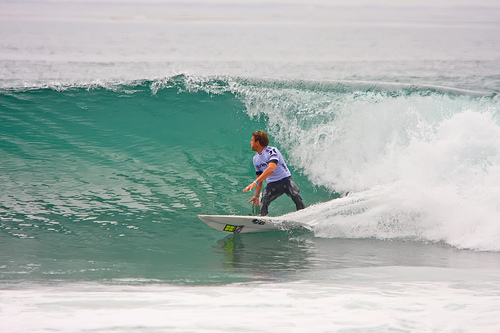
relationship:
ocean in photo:
[28, 37, 479, 187] [31, 19, 487, 318]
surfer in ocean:
[247, 112, 305, 220] [28, 37, 479, 187]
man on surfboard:
[252, 127, 299, 237] [194, 209, 295, 223]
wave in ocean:
[347, 108, 447, 227] [28, 37, 479, 187]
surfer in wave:
[247, 112, 305, 220] [347, 108, 447, 227]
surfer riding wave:
[247, 112, 305, 220] [347, 108, 447, 227]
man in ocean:
[252, 127, 299, 237] [28, 37, 479, 187]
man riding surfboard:
[252, 127, 299, 237] [194, 209, 295, 223]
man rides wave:
[252, 127, 299, 237] [347, 108, 447, 227]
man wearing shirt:
[252, 127, 299, 237] [251, 151, 297, 181]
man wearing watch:
[252, 127, 299, 237] [253, 181, 258, 187]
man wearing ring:
[252, 127, 299, 237] [245, 186, 249, 192]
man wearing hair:
[252, 127, 299, 237] [259, 133, 267, 143]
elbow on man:
[268, 169, 273, 176] [252, 127, 299, 237]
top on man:
[251, 151, 297, 181] [252, 127, 299, 237]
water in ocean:
[31, 115, 256, 207] [28, 37, 479, 187]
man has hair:
[252, 127, 299, 237] [259, 133, 267, 143]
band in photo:
[255, 190, 262, 199] [31, 19, 487, 318]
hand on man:
[240, 182, 253, 193] [252, 127, 299, 237]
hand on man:
[251, 195, 260, 207] [252, 127, 299, 237]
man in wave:
[252, 127, 299, 237] [347, 108, 447, 227]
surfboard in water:
[194, 209, 295, 223] [31, 115, 256, 207]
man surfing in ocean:
[252, 127, 299, 237] [28, 37, 479, 187]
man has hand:
[252, 127, 299, 237] [240, 182, 253, 193]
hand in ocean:
[240, 182, 253, 193] [28, 37, 479, 187]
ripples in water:
[111, 160, 223, 206] [31, 115, 256, 207]